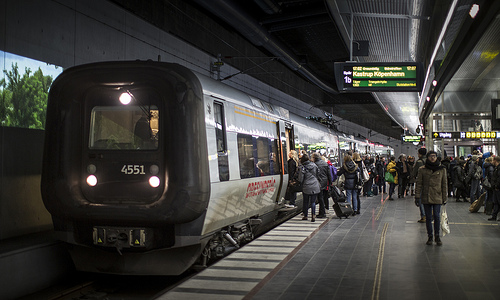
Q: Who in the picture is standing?
A: The people are standing.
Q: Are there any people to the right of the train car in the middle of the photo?
A: Yes, there are people to the right of the train car.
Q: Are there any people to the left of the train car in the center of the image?
A: No, the people are to the right of the train car.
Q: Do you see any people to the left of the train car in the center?
A: No, the people are to the right of the train car.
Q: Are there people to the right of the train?
A: Yes, there are people to the right of the train.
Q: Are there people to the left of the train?
A: No, the people are to the right of the train.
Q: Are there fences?
A: No, there are no fences.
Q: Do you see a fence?
A: No, there are no fences.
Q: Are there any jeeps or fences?
A: No, there are no fences or jeeps.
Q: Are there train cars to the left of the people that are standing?
A: Yes, there is a train car to the left of the people.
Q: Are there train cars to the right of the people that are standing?
A: No, the train car is to the left of the people.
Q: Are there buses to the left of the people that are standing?
A: No, there is a train car to the left of the people.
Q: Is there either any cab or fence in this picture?
A: No, there are no fences or taxis.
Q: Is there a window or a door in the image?
A: Yes, there is a window.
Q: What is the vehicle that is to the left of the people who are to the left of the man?
A: The vehicle is a train car.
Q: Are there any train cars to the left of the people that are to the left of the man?
A: Yes, there is a train car to the left of the people.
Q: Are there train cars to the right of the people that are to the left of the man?
A: No, the train car is to the left of the people.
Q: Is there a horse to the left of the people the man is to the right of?
A: No, there is a train car to the left of the people.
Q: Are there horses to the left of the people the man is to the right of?
A: No, there is a train car to the left of the people.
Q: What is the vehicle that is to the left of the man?
A: The vehicle is a train car.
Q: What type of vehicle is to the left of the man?
A: The vehicle is a train car.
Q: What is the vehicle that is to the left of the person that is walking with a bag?
A: The vehicle is a train car.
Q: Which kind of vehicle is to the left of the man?
A: The vehicle is a train car.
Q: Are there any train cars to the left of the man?
A: Yes, there is a train car to the left of the man.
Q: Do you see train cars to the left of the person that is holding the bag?
A: Yes, there is a train car to the left of the man.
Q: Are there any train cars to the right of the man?
A: No, the train car is to the left of the man.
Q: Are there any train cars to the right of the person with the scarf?
A: No, the train car is to the left of the man.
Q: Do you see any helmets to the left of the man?
A: No, there is a train car to the left of the man.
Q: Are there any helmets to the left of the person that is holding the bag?
A: No, there is a train car to the left of the man.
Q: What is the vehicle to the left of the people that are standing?
A: The vehicle is a train car.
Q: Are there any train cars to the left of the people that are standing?
A: Yes, there is a train car to the left of the people.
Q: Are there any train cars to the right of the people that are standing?
A: No, the train car is to the left of the people.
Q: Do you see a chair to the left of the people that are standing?
A: No, there is a train car to the left of the people.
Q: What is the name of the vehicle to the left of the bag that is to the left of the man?
A: The vehicle is a train car.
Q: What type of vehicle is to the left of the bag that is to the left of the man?
A: The vehicle is a train car.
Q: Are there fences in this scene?
A: No, there are no fences.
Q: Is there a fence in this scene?
A: No, there are no fences.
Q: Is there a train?
A: Yes, there is a train.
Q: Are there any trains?
A: Yes, there is a train.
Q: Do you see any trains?
A: Yes, there is a train.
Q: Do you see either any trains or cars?
A: Yes, there is a train.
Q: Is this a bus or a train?
A: This is a train.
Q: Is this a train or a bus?
A: This is a train.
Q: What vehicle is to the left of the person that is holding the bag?
A: The vehicle is a train.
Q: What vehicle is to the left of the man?
A: The vehicle is a train.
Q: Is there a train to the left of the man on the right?
A: Yes, there is a train to the left of the man.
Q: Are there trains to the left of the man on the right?
A: Yes, there is a train to the left of the man.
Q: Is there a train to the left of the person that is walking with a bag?
A: Yes, there is a train to the left of the man.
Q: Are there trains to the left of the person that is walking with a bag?
A: Yes, there is a train to the left of the man.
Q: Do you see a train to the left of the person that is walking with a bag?
A: Yes, there is a train to the left of the man.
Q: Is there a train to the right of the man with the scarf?
A: No, the train is to the left of the man.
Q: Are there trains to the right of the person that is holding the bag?
A: No, the train is to the left of the man.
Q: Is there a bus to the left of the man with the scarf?
A: No, there is a train to the left of the man.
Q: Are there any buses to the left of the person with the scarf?
A: No, there is a train to the left of the man.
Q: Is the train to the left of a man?
A: Yes, the train is to the left of a man.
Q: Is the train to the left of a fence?
A: No, the train is to the left of a man.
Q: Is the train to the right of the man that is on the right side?
A: No, the train is to the left of the man.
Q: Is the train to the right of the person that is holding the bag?
A: No, the train is to the left of the man.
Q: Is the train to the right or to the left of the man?
A: The train is to the left of the man.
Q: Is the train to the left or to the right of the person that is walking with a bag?
A: The train is to the left of the man.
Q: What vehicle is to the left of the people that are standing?
A: The vehicle is a train.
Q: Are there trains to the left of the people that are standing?
A: Yes, there is a train to the left of the people.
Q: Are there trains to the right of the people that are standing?
A: No, the train is to the left of the people.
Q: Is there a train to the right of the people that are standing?
A: No, the train is to the left of the people.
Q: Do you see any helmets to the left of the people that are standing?
A: No, there is a train to the left of the people.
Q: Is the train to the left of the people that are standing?
A: Yes, the train is to the left of the people.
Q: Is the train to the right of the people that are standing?
A: No, the train is to the left of the people.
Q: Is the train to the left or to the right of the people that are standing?
A: The train is to the left of the people.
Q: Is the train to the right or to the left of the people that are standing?
A: The train is to the left of the people.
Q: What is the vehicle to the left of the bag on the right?
A: The vehicle is a train.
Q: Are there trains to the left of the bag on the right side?
A: Yes, there is a train to the left of the bag.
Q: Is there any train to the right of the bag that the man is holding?
A: No, the train is to the left of the bag.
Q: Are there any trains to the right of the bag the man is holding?
A: No, the train is to the left of the bag.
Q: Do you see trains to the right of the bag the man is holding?
A: No, the train is to the left of the bag.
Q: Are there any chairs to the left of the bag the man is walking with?
A: No, there is a train to the left of the bag.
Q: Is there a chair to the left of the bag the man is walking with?
A: No, there is a train to the left of the bag.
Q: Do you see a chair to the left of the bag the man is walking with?
A: No, there is a train to the left of the bag.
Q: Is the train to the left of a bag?
A: Yes, the train is to the left of a bag.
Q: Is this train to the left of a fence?
A: No, the train is to the left of a bag.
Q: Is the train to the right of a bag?
A: No, the train is to the left of a bag.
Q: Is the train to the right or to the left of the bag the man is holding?
A: The train is to the left of the bag.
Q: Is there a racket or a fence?
A: No, there are no fences or rackets.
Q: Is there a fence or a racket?
A: No, there are no fences or rackets.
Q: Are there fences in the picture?
A: No, there are no fences.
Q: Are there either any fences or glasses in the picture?
A: No, there are no fences or glasses.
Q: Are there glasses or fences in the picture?
A: No, there are no fences or glasses.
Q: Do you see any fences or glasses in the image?
A: No, there are no fences or glasses.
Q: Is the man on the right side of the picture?
A: Yes, the man is on the right of the image.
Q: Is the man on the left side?
A: No, the man is on the right of the image.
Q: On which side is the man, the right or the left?
A: The man is on the right of the image.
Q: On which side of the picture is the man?
A: The man is on the right of the image.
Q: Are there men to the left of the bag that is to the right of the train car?
A: No, the man is to the right of the bag.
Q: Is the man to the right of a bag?
A: Yes, the man is to the right of a bag.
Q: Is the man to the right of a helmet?
A: No, the man is to the right of a bag.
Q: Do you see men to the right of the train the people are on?
A: Yes, there is a man to the right of the train.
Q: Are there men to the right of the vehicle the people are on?
A: Yes, there is a man to the right of the train.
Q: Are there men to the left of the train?
A: No, the man is to the right of the train.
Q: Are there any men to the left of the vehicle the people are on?
A: No, the man is to the right of the train.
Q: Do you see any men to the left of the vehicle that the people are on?
A: No, the man is to the right of the train.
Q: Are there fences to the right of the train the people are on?
A: No, there is a man to the right of the train.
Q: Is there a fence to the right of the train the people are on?
A: No, there is a man to the right of the train.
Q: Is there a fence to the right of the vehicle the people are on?
A: No, there is a man to the right of the train.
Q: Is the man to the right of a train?
A: Yes, the man is to the right of a train.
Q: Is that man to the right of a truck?
A: No, the man is to the right of a train.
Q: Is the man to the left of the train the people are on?
A: No, the man is to the right of the train.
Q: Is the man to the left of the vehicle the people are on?
A: No, the man is to the right of the train.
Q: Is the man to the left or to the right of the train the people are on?
A: The man is to the right of the train.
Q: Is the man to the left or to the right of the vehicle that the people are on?
A: The man is to the right of the train.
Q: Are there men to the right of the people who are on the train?
A: Yes, there is a man to the right of the people.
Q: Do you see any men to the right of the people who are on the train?
A: Yes, there is a man to the right of the people.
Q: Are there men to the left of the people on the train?
A: No, the man is to the right of the people.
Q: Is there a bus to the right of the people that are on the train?
A: No, there is a man to the right of the people.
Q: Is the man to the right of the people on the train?
A: Yes, the man is to the right of the people.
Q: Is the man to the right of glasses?
A: No, the man is to the right of the people.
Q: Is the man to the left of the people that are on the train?
A: No, the man is to the right of the people.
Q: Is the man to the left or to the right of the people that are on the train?
A: The man is to the right of the people.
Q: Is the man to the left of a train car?
A: No, the man is to the right of a train car.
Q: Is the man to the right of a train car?
A: Yes, the man is to the right of a train car.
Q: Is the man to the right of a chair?
A: No, the man is to the right of a train car.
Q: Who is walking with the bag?
A: The man is walking with the bag.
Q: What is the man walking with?
A: The man is walking with a bag.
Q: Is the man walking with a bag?
A: Yes, the man is walking with a bag.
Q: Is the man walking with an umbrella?
A: No, the man is walking with a bag.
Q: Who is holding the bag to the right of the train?
A: The man is holding the bag.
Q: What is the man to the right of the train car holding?
A: The man is holding the bag.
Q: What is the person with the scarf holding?
A: The man is holding the bag.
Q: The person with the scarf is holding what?
A: The man is holding the bag.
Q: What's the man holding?
A: The man is holding the bag.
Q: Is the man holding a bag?
A: Yes, the man is holding a bag.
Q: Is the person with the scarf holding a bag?
A: Yes, the man is holding a bag.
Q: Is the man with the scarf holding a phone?
A: No, the man is holding a bag.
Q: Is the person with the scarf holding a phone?
A: No, the man is holding a bag.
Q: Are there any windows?
A: Yes, there is a window.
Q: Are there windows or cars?
A: Yes, there is a window.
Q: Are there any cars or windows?
A: Yes, there is a window.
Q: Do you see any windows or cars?
A: Yes, there is a window.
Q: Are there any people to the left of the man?
A: Yes, there are people to the left of the man.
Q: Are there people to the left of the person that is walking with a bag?
A: Yes, there are people to the left of the man.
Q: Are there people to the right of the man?
A: No, the people are to the left of the man.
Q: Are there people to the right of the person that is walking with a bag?
A: No, the people are to the left of the man.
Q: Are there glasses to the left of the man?
A: No, there are people to the left of the man.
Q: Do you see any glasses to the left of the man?
A: No, there are people to the left of the man.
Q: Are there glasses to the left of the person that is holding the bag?
A: No, there are people to the left of the man.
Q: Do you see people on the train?
A: Yes, there are people on the train.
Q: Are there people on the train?
A: Yes, there are people on the train.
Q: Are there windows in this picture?
A: Yes, there is a window.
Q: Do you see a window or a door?
A: Yes, there is a window.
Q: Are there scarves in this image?
A: Yes, there is a scarf.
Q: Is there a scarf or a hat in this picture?
A: Yes, there is a scarf.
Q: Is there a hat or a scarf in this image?
A: Yes, there is a scarf.